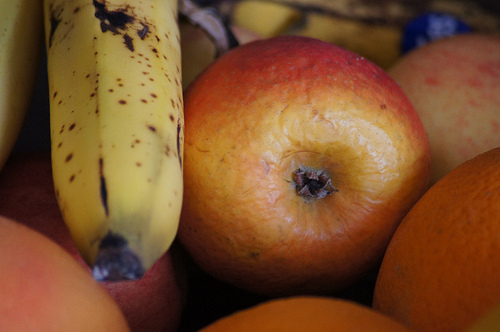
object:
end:
[91, 227, 144, 281]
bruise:
[92, 0, 137, 36]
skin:
[0, 213, 134, 332]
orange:
[200, 295, 404, 332]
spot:
[121, 33, 135, 52]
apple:
[175, 35, 434, 299]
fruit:
[0, 214, 132, 332]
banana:
[42, 1, 185, 284]